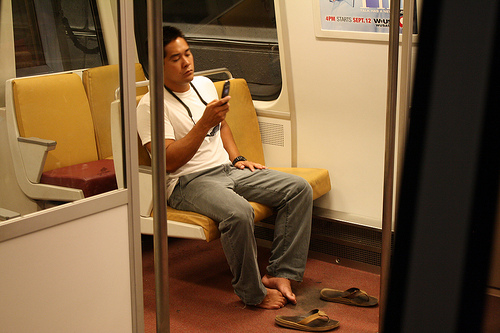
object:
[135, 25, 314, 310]
man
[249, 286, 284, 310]
feet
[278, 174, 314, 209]
knee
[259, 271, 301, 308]
feet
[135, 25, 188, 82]
hair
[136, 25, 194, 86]
head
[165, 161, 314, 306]
jeans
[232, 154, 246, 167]
watch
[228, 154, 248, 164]
wrist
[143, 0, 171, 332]
pole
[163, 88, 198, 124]
chain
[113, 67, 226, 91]
bar seat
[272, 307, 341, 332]
sandal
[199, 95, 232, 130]
hand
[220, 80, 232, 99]
cell phone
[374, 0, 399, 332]
pole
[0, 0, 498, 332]
subway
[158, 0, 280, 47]
window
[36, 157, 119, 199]
cushion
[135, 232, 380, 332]
floor